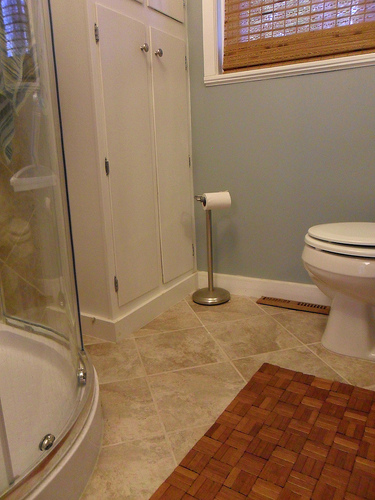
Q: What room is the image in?
A: It is at the bathroom.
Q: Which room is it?
A: It is a bathroom.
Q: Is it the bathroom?
A: Yes, it is the bathroom.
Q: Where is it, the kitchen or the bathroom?
A: It is the bathroom.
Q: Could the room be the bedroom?
A: No, it is the bathroom.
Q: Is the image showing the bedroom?
A: No, the picture is showing the bathroom.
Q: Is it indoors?
A: Yes, it is indoors.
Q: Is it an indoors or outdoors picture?
A: It is indoors.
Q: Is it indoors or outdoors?
A: It is indoors.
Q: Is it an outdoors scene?
A: No, it is indoors.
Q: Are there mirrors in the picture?
A: No, there are no mirrors.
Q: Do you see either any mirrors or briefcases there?
A: No, there are no mirrors or briefcases.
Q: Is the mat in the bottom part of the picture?
A: Yes, the mat is in the bottom of the image.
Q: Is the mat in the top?
A: No, the mat is in the bottom of the image.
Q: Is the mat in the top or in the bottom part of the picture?
A: The mat is in the bottom of the image.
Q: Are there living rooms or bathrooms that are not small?
A: No, there is a bathroom but it is small.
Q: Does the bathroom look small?
A: Yes, the bathroom is small.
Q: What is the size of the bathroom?
A: The bathroom is small.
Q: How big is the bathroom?
A: The bathroom is small.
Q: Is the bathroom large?
A: No, the bathroom is small.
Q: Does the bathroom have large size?
A: No, the bathroom is small.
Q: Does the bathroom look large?
A: No, the bathroom is small.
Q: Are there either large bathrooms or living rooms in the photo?
A: No, there is a bathroom but it is small.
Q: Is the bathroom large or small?
A: The bathroom is small.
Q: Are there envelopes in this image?
A: No, there are no envelopes.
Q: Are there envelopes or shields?
A: No, there are no envelopes or shields.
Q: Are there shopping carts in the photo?
A: No, there are no shopping carts.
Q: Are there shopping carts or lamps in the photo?
A: No, there are no shopping carts or lamps.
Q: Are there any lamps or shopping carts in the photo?
A: No, there are no shopping carts or lamps.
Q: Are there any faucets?
A: No, there are no faucets.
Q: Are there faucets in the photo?
A: No, there are no faucets.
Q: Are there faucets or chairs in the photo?
A: No, there are no faucets or chairs.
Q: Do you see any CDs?
A: No, there are no cds.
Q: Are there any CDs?
A: No, there are no cds.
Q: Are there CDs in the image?
A: No, there are no cds.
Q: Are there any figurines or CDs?
A: No, there are no CDs or figurines.